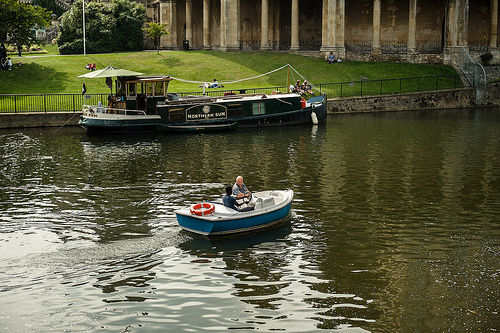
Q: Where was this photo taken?
A: Near the water.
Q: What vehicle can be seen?
A: Boat.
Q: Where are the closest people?
A: In the small boat.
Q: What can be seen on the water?
A: Reflection of sun.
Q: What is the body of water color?
A: Green.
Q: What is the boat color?
A: Aqua blue.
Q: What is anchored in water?
A: Large boat.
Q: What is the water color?
A: Green.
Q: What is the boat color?
A: White and blue.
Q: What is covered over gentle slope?
A: Grass.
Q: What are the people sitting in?
A: A boat.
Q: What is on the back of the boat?
A: Float.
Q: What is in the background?
A: A building.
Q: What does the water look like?
A: Calm and murky.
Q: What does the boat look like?
A: White and blue.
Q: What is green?
A: Grass.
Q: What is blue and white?
A: Boat.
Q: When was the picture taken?
A: Daytime.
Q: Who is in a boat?
A: Two people.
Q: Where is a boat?
A: In the water.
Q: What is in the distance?
A: Trees.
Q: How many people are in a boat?
A: Two.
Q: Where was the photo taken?
A: In a park lake.